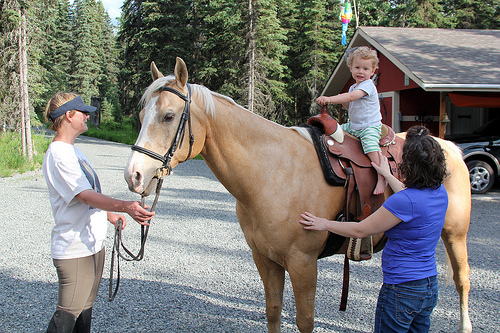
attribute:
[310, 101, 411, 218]
saddle — brown, black, leather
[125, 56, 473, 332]
horse — sleepy, tan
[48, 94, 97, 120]
visor — black, blue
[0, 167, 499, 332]
parking lot — gravel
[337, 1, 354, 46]
windsock — colorful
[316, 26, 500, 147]
building — a country home, red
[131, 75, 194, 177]
bridle — dark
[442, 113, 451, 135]
dinner bell — old fashioned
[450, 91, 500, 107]
awning — scarlet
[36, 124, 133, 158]
driveway — heading off, gravel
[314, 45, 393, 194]
child — little, barefoot, blond, scared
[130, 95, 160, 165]
design — white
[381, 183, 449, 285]
shirt — blue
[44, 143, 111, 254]
shirt — white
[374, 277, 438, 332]
jeans — blue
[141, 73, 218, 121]
mane — white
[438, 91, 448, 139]
column — wood